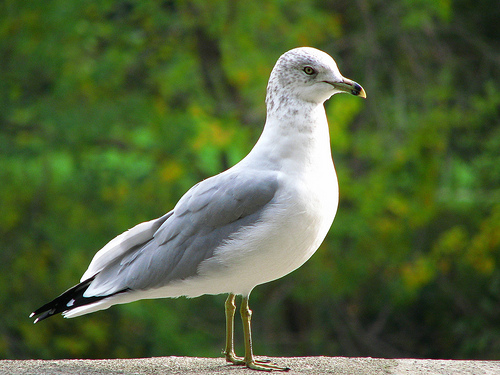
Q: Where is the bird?
A: On the cement.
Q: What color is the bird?
A: White, gray, and black.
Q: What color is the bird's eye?
A: Yellow and black.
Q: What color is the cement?
A: Gray.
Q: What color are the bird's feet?
A: Yellow.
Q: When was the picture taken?
A: Daytime.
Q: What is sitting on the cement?
A: The bird.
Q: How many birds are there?
A: One.